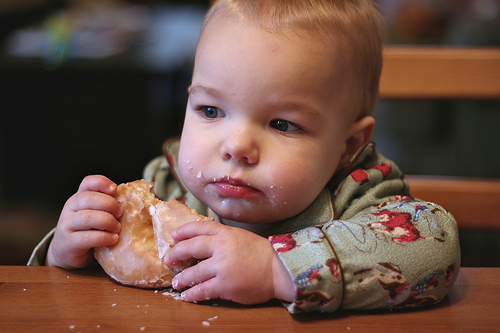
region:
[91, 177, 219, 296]
donut in babies hands on table top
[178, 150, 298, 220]
donut icing around babies mouth on face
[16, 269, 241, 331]
crumbs from donut scattered on table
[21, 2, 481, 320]
baby in pajamas leaning on table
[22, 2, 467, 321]
baby eating donut leaning on table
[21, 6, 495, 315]
baby sitting in chair eating donut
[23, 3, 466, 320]
baby with dusty blonde hair eating donut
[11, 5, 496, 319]
baby sitting in chair looking dazed to the left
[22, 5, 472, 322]
baby in colorful pajamas leaning on table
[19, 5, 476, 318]
dirty blonde baby in middle of picture eating donut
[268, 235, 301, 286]
edge of a sleeve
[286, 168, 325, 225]
part of a cheek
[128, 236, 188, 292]
part of a finger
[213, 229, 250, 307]
aprt of a hand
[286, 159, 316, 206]
part f a cheek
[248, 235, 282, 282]
aprt fo a lie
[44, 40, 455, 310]
the baby is eating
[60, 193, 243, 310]
donut in the hands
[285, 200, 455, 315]
pattern on the sleeve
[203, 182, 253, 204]
mouth of the baby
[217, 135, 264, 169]
nose of the baby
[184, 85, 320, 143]
eye of the baby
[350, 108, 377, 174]
ear of the baby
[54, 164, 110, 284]
hand of the baby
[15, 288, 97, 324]
the table is wood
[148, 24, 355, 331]
ypung kid staring in the air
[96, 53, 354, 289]
boy is eating a snack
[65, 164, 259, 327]
boy is holding a snack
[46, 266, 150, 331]
floor is brown in color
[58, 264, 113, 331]
the surface is wooden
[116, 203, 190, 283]
the snack is bropwn in color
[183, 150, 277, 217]
mouth has the snack crunches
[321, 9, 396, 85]
the hair is brown in color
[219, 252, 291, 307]
the baby is light skinned